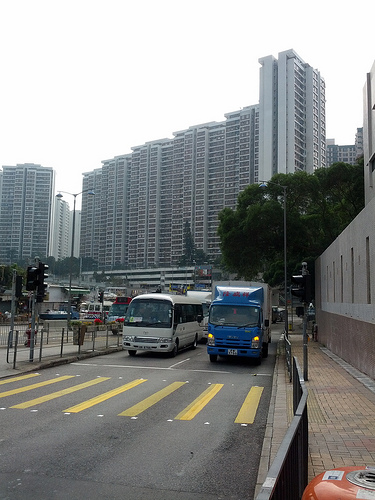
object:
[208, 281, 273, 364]
truck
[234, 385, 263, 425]
line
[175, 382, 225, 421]
line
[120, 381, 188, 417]
line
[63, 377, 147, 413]
line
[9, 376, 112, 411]
line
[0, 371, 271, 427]
walkway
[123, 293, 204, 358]
bus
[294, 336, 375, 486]
sidewalk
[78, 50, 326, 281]
building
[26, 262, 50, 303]
traffic light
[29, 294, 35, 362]
pole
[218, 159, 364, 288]
trees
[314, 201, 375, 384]
wall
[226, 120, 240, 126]
window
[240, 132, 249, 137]
window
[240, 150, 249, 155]
window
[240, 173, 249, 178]
window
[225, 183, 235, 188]
window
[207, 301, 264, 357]
front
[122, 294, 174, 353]
front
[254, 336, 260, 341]
headlight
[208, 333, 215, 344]
headlight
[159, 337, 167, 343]
headlight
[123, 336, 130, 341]
headlight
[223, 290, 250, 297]
writing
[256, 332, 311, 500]
barrier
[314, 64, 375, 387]
building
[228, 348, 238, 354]
license plate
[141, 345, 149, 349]
license plate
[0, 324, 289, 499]
road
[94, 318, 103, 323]
flowers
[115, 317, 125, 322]
flowers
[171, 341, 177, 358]
wheel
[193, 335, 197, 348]
wheel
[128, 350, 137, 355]
wheel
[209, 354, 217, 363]
wheel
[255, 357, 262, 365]
wheel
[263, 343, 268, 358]
wheel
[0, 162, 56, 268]
building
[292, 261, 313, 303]
traffic light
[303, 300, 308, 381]
pole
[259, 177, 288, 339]
light pole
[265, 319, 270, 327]
side mirror